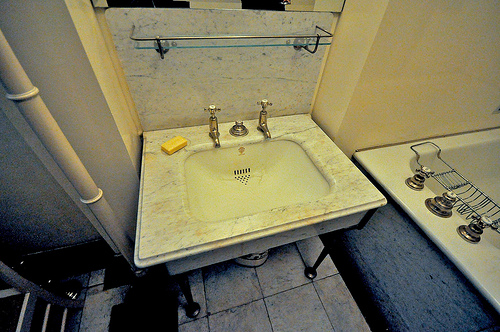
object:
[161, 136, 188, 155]
soap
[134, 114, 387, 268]
sink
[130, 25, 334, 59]
shelf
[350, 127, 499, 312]
tub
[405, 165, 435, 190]
faucets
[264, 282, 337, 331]
tile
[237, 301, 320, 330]
floor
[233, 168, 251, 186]
drain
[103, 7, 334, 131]
backsplash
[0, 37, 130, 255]
pipe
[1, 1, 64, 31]
wall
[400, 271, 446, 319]
marble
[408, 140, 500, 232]
rack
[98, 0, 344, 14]
mirror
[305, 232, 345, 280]
leg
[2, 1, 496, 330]
bathroom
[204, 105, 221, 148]
faucets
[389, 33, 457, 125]
wall